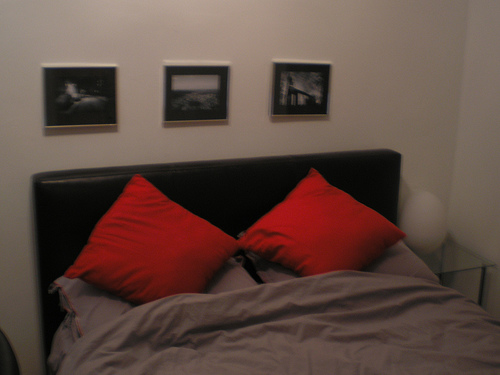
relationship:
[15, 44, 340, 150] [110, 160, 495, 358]
picture above bed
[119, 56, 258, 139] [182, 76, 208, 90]
black and white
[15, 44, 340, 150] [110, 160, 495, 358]
wall next to bed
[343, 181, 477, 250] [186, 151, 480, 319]
light on stand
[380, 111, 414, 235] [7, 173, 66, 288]
wall behind post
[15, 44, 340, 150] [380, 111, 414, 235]
picture on wall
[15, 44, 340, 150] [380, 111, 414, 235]
picture of wall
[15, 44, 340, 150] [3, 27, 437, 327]
picture in frame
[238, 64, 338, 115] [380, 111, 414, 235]
photograph on wall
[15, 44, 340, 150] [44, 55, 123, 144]
picture in frame